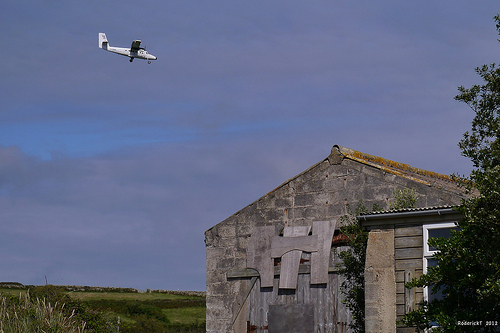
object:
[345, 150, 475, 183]
moss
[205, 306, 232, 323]
grey stone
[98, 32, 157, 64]
aeroplane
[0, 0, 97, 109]
clouds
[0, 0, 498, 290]
sky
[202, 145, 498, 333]
building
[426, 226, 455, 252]
window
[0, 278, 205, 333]
fields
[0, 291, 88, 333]
plant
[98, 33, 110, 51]
tail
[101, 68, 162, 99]
clouds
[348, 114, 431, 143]
clouds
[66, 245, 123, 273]
clouds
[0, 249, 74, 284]
clouds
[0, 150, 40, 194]
clouds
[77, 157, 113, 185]
clouds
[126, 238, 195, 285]
clouds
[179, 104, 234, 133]
clouds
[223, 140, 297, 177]
clouds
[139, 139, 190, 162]
clouds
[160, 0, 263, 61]
clouds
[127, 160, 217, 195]
air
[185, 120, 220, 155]
clouds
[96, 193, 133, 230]
clouds